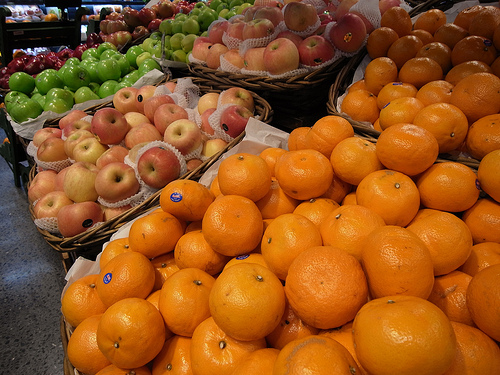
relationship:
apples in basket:
[68, 122, 145, 189] [182, 44, 353, 112]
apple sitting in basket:
[54, 200, 103, 242] [26, 75, 274, 271]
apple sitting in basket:
[94, 160, 143, 204] [26, 75, 274, 271]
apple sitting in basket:
[135, 141, 183, 189] [26, 75, 274, 271]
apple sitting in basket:
[71, 137, 106, 163] [26, 75, 274, 271]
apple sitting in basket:
[159, 116, 204, 153] [26, 75, 274, 271]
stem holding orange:
[253, 272, 264, 282] [209, 259, 284, 341]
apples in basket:
[264, 38, 300, 74] [186, 59, 342, 94]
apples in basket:
[331, 14, 368, 54] [186, 59, 342, 94]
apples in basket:
[216, 105, 254, 135] [186, 59, 342, 94]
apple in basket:
[163, 118, 202, 155] [186, 59, 342, 94]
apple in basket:
[135, 144, 183, 189] [186, 59, 342, 94]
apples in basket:
[93, 105, 127, 142] [186, 59, 342, 94]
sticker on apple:
[80, 216, 97, 230] [53, 199, 104, 240]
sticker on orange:
[103, 268, 113, 287] [90, 252, 154, 304]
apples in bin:
[192, 139, 408, 372] [4, 29, 184, 149]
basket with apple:
[29, 70, 279, 271] [135, 144, 183, 189]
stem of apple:
[113, 171, 120, 181] [93, 161, 140, 200]